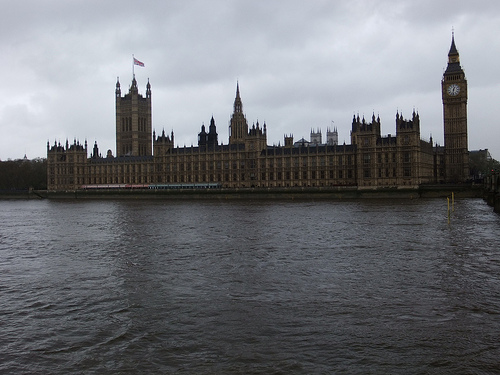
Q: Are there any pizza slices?
A: No, there are no pizza slices.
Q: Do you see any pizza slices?
A: No, there are no pizza slices.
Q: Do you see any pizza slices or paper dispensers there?
A: No, there are no pizza slices or paper dispensers.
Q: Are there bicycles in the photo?
A: No, there are no bicycles.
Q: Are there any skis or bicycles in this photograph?
A: No, there are no bicycles or skis.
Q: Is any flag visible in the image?
A: Yes, there is a flag.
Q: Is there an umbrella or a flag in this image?
A: Yes, there is a flag.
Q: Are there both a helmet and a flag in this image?
A: No, there is a flag but no helmets.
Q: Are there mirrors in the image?
A: No, there are no mirrors.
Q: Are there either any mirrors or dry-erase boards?
A: No, there are no mirrors or dry-erase boards.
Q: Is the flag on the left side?
A: Yes, the flag is on the left of the image.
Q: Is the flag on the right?
A: No, the flag is on the left of the image.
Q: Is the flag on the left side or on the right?
A: The flag is on the left of the image.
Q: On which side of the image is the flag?
A: The flag is on the left of the image.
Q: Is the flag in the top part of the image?
A: Yes, the flag is in the top of the image.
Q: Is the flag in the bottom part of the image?
A: No, the flag is in the top of the image.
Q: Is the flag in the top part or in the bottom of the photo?
A: The flag is in the top of the image.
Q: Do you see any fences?
A: No, there are no fences.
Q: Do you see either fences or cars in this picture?
A: No, there are no fences or cars.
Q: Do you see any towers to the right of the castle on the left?
A: Yes, there is a tower to the right of the castle.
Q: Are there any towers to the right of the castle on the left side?
A: Yes, there is a tower to the right of the castle.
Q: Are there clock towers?
A: Yes, there is a clock tower.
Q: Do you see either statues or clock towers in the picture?
A: Yes, there is a clock tower.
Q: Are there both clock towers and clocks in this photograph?
A: Yes, there are both a clock tower and a clock.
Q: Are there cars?
A: No, there are no cars.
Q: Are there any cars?
A: No, there are no cars.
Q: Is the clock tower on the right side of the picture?
A: Yes, the clock tower is on the right of the image.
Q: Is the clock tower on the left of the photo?
A: No, the clock tower is on the right of the image.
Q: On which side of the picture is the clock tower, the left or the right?
A: The clock tower is on the right of the image.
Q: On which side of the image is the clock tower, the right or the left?
A: The clock tower is on the right of the image.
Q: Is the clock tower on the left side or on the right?
A: The clock tower is on the right of the image.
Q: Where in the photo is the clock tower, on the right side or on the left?
A: The clock tower is on the right of the image.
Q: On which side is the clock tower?
A: The clock tower is on the right of the image.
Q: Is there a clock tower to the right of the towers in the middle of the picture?
A: Yes, there is a clock tower to the right of the towers.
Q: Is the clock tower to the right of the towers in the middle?
A: Yes, the clock tower is to the right of the towers.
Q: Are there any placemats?
A: No, there are no placemats.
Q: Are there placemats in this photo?
A: No, there are no placemats.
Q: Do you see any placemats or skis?
A: No, there are no placemats or skis.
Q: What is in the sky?
A: The clouds are in the sky.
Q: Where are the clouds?
A: The clouds are in the sky.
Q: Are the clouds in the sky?
A: Yes, the clouds are in the sky.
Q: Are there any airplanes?
A: No, there are no airplanes.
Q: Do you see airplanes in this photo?
A: No, there are no airplanes.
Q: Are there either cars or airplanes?
A: No, there are no airplanes or cars.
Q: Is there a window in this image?
A: Yes, there are windows.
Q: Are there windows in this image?
A: Yes, there are windows.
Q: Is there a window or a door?
A: Yes, there are windows.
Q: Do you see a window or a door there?
A: Yes, there are windows.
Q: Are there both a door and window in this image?
A: No, there are windows but no doors.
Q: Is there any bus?
A: No, there are no buses.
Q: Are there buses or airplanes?
A: No, there are no buses or airplanes.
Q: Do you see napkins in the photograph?
A: No, there are no napkins.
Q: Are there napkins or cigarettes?
A: No, there are no napkins or cigarettes.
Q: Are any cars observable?
A: No, there are no cars.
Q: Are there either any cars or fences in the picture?
A: No, there are no cars or fences.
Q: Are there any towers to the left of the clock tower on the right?
A: Yes, there are towers to the left of the clock tower.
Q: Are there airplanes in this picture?
A: No, there are no airplanes.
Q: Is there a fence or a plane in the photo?
A: No, there are no airplanes or fences.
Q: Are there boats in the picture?
A: No, there are no boats.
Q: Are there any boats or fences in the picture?
A: No, there are no boats or fences.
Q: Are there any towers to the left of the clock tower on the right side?
A: Yes, there are towers to the left of the clock tower.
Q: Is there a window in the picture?
A: Yes, there are windows.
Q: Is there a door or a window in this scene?
A: Yes, there are windows.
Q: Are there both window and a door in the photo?
A: No, there are windows but no doors.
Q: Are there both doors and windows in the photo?
A: No, there are windows but no doors.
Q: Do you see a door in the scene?
A: No, there are no doors.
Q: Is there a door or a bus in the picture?
A: No, there are no doors or buses.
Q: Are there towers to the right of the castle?
A: Yes, there are towers to the right of the castle.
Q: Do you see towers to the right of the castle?
A: Yes, there are towers to the right of the castle.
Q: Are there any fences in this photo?
A: No, there are no fences.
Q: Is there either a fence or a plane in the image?
A: No, there are no fences or airplanes.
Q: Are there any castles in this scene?
A: Yes, there is a castle.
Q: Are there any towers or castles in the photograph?
A: Yes, there is a castle.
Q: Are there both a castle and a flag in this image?
A: Yes, there are both a castle and a flag.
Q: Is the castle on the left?
A: Yes, the castle is on the left of the image.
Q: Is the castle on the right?
A: No, the castle is on the left of the image.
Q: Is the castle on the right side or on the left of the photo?
A: The castle is on the left of the image.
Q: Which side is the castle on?
A: The castle is on the left of the image.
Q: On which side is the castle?
A: The castle is on the left of the image.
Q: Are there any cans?
A: No, there are no cans.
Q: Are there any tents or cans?
A: No, there are no cans or tents.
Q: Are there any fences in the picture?
A: No, there are no fences.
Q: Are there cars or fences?
A: No, there are no fences or cars.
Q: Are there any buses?
A: No, there are no buses.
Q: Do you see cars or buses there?
A: No, there are no buses or cars.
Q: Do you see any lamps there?
A: No, there are no lamps.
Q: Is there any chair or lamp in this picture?
A: No, there are no lamps or chairs.